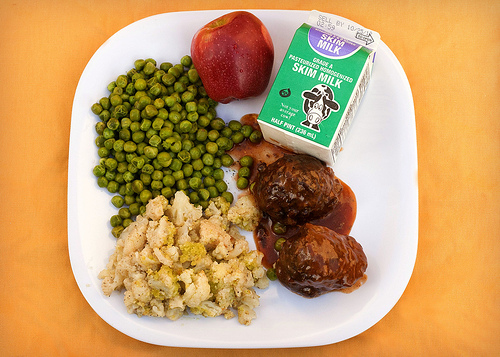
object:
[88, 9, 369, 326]
food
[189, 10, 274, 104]
apple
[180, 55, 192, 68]
pea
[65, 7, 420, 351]
plate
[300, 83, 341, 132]
cow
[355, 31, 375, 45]
arrow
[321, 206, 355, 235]
sauce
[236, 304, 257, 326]
chunk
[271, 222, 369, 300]
meatball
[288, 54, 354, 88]
letters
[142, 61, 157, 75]
pea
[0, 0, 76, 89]
tabletop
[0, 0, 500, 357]
table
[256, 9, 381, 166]
carton